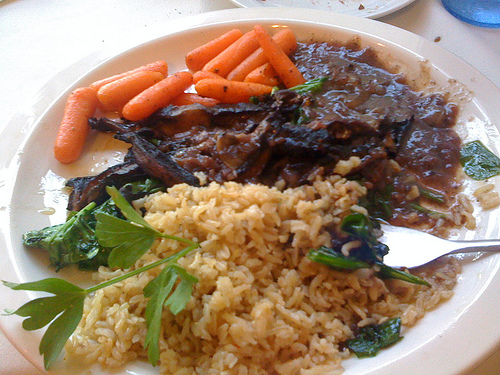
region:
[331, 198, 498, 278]
a fork sticking in the rice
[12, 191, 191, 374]
a large piece of parsley in the food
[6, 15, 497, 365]
a large plate of food served on a white plate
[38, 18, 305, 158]
plain cooked carrots on the plate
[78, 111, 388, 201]
some stewed red meat in the middle of the plate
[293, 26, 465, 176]
some brown sauce or gravy on the edge of the plate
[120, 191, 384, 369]
a large helping of seasoned rice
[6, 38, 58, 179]
the edge of the white plate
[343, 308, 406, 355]
a green leaf of one of the spices in the food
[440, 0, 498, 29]
the edge of the blue dish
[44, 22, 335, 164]
baby carrots on plate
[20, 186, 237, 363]
green garnish on plate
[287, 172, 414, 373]
bits of spinach on plate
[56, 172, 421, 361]
savory rice on plate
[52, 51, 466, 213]
bbq chicken on plate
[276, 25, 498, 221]
brown gravy on plate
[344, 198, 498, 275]
silver fork on plate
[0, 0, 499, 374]
white round plate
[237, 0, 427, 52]
round small white plate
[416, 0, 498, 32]
blue tumbler cup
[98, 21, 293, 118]
orange steamed baby carrots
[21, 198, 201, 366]
parley leaves garnish stuck in rice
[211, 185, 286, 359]
bed of brown sticky rice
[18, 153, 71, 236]
light reflected on white china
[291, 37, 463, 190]
brown sauce on side of plate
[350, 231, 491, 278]
silver fork partially under food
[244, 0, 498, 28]
blue and white dishes nearby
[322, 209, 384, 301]
wilted green vegetables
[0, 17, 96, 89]
white table under the plate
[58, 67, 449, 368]
plate full of food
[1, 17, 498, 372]
a dish with rice and meats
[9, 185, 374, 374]
yellow rice is topped with parsley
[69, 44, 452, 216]
a stew meat is on the dish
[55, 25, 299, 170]
small baby carrots on the dish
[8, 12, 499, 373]
the plate is white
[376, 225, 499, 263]
a silver fork is in the food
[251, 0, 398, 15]
there is a dirty plate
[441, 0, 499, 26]
there is a blue plate on the side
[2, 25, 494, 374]
the plate is full of food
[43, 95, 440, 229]
the meat looks juicy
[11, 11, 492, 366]
Three food items on the plate.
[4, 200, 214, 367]
Parsley is on the dish.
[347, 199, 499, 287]
A fork is on the plate under the rice.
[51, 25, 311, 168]
Twelve baby carrots are on the plate.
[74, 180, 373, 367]
The rice is yellow.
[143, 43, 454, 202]
The meat has sauce on it.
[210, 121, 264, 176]
A piece of mushroom is mixed with the meat.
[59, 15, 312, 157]
The carrots are next to the meat.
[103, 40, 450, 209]
The meat is next to the rice.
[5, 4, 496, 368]
The plate has a slight indentation for the food.